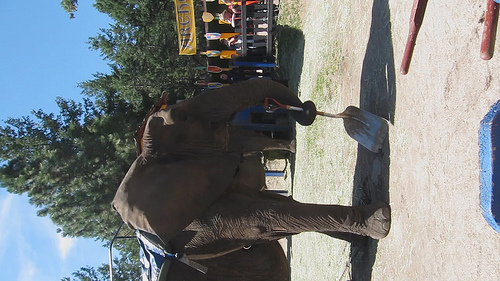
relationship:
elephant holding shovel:
[115, 76, 393, 280] [261, 96, 394, 154]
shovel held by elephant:
[261, 96, 394, 154] [115, 76, 393, 280]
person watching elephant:
[218, 10, 237, 23] [115, 76, 393, 280]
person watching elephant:
[223, 35, 242, 48] [115, 76, 393, 280]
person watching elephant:
[218, 71, 237, 81] [115, 76, 393, 280]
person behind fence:
[218, 10, 237, 23] [232, 2, 289, 70]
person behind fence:
[223, 35, 242, 48] [232, 2, 289, 70]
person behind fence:
[218, 71, 237, 81] [232, 2, 289, 70]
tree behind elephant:
[76, 63, 211, 105] [115, 76, 393, 280]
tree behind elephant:
[86, 21, 201, 76] [115, 76, 393, 280]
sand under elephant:
[266, 2, 498, 280] [115, 76, 393, 280]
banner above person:
[172, 1, 199, 56] [218, 10, 237, 23]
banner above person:
[172, 1, 199, 56] [223, 35, 242, 48]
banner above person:
[172, 1, 199, 56] [218, 71, 237, 81]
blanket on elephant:
[134, 232, 211, 280] [115, 76, 393, 280]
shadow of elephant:
[347, 1, 396, 281] [115, 76, 393, 280]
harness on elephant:
[174, 246, 258, 275] [115, 76, 393, 280]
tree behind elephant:
[0, 90, 171, 258] [115, 76, 393, 280]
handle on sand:
[399, 1, 428, 74] [266, 2, 498, 280]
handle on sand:
[480, 1, 500, 58] [266, 2, 498, 280]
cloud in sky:
[58, 232, 77, 261] [0, 1, 137, 280]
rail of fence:
[241, 0, 251, 60] [232, 2, 289, 70]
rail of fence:
[266, 2, 275, 62] [232, 2, 289, 70]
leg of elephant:
[217, 190, 391, 241] [115, 76, 393, 280]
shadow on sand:
[347, 1, 396, 281] [266, 2, 498, 280]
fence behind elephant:
[232, 2, 289, 70] [115, 76, 393, 280]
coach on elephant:
[109, 224, 145, 280] [115, 76, 393, 280]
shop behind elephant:
[174, 1, 247, 95] [115, 76, 393, 280]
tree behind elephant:
[52, 255, 142, 280] [115, 76, 393, 280]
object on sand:
[478, 100, 499, 231] [266, 2, 498, 280]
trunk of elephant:
[206, 76, 317, 133] [115, 76, 393, 280]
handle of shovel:
[263, 97, 289, 117] [261, 96, 394, 154]